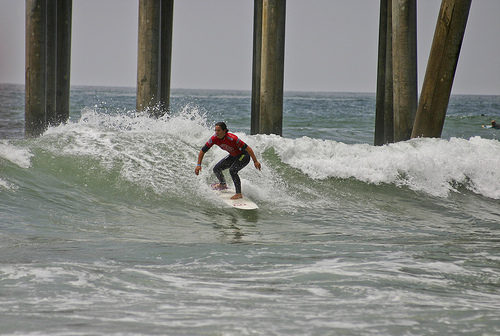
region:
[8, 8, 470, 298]
surfer riding the waves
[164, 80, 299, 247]
woman surfing in red and black wetsuit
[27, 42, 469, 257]
surfing waves under ocean pier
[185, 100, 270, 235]
woman on white surf board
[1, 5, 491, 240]
poles beneath ocean pier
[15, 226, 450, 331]
blue green ocean water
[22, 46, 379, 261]
white crest of ocean wave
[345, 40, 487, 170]
white wave breaking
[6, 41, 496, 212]
horizon where ocean meets sky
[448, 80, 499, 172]
surfers floating in ocean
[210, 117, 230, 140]
the head of a man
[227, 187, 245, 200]
the foot of a man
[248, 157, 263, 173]
the hand of a man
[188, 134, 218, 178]
the arm of a man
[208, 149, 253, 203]
the legs of a man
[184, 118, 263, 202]
a man on a surfboard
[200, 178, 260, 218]
a white surfboard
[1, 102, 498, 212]
a white wave behind the man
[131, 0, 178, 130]
a brown wooden support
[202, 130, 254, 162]
a red shirt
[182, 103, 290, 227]
Girl surfing in water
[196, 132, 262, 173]
Red swimsuit on girl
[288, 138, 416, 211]
White waves in water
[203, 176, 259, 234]
White surfboard on girl's feet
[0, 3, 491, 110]
Brown pillars of pier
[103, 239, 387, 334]
still ocean water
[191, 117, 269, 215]
Girl in surfing position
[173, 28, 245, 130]
Ocean in the distance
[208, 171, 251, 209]
Bare feet of surfer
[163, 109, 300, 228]
surfer riding a wave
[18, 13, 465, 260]
surfing in the ocean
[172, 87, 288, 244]
woman surfing on white board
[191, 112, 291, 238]
woman wearing red and black wet suit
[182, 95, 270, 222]
experienced surfer riding wave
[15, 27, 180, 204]
waves crashing against pier pole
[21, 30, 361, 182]
surfing too close to to the pier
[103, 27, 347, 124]
horizon where ocean meets sky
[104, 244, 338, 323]
blue green ocean water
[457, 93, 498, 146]
swimmers in the distance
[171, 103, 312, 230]
professional female surfer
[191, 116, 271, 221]
female surfer riding waves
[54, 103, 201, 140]
white foam from the waves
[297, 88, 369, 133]
blue ocean water in the background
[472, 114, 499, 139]
surfer in the ocean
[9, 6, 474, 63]
wood holding up the pier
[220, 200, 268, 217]
front of the white surfboard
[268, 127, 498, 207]
wave crashing in the ocean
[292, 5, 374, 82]
blue grey sky in the distance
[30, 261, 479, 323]
ocean waters in front of wave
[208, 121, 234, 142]
face of a female surfer